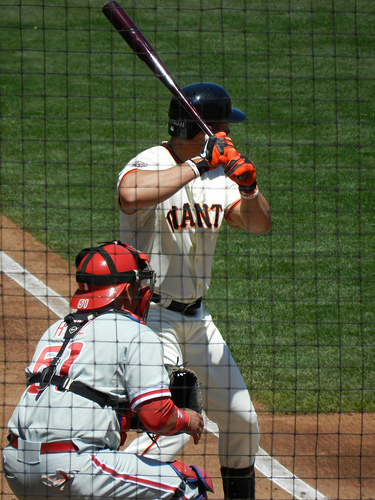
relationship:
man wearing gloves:
[114, 77, 274, 498] [183, 123, 264, 199]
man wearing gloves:
[114, 77, 274, 498] [187, 127, 266, 200]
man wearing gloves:
[114, 77, 274, 498] [185, 123, 262, 208]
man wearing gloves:
[114, 77, 274, 498] [193, 128, 260, 195]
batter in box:
[97, 5, 277, 486] [28, 364, 312, 498]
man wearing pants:
[114, 77, 282, 484] [124, 296, 260, 484]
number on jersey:
[24, 347, 76, 389] [14, 312, 168, 451]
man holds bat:
[114, 77, 274, 498] [64, 16, 246, 166]